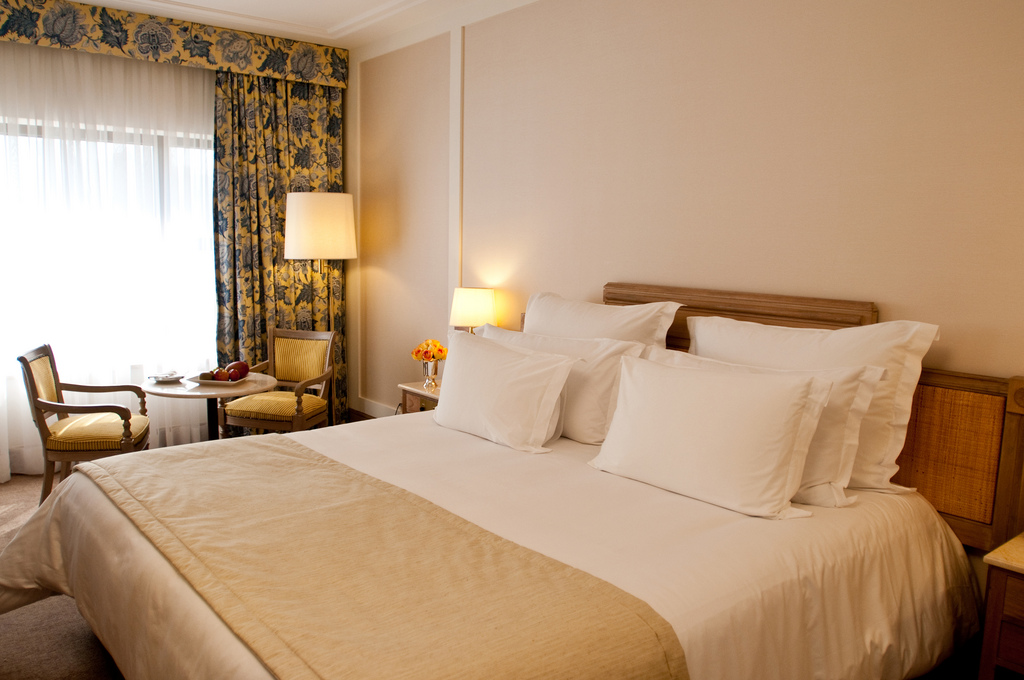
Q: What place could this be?
A: It is a hotel room.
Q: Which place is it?
A: It is a hotel room.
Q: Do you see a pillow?
A: Yes, there is a pillow.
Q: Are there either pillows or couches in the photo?
A: Yes, there is a pillow.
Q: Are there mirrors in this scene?
A: No, there are no mirrors.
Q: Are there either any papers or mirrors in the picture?
A: No, there are no mirrors or papers.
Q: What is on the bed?
A: The pillow is on the bed.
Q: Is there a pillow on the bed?
A: Yes, there is a pillow on the bed.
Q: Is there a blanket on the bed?
A: No, there is a pillow on the bed.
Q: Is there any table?
A: Yes, there is a table.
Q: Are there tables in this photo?
A: Yes, there is a table.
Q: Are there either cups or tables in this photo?
A: Yes, there is a table.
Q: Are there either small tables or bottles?
A: Yes, there is a small table.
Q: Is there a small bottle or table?
A: Yes, there is a small table.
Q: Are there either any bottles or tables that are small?
A: Yes, the table is small.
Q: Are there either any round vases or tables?
A: Yes, there is a round table.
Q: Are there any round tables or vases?
A: Yes, there is a round table.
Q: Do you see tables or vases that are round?
A: Yes, the table is round.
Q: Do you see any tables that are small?
A: Yes, there is a small table.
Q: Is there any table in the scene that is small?
A: Yes, there is a table that is small.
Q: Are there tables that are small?
A: Yes, there is a table that is small.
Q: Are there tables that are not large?
A: Yes, there is a small table.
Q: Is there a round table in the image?
A: Yes, there is a round table.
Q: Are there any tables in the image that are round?
A: Yes, there is a table that is round.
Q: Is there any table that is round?
A: Yes, there is a table that is round.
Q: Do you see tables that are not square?
A: Yes, there is a round table.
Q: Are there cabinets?
A: No, there are no cabinets.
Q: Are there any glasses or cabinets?
A: No, there are no cabinets or glasses.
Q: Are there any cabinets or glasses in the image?
A: No, there are no cabinets or glasses.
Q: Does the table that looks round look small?
A: Yes, the table is small.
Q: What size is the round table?
A: The table is small.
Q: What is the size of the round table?
A: The table is small.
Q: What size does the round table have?
A: The table has small size.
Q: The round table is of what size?
A: The table is small.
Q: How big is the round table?
A: The table is small.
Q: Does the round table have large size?
A: No, the table is small.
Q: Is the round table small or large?
A: The table is small.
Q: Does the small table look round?
A: Yes, the table is round.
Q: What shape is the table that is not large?
A: The table is round.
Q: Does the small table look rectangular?
A: No, the table is round.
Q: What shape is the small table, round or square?
A: The table is round.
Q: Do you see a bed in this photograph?
A: Yes, there is a bed.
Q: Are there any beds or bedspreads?
A: Yes, there is a bed.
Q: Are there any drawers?
A: No, there are no drawers.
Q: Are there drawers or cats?
A: No, there are no drawers or cats.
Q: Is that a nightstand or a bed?
A: That is a bed.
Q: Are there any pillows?
A: Yes, there is a pillow.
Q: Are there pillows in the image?
A: Yes, there is a pillow.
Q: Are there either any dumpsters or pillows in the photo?
A: Yes, there is a pillow.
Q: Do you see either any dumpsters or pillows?
A: Yes, there is a pillow.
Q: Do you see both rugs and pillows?
A: No, there is a pillow but no rugs.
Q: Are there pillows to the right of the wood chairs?
A: Yes, there is a pillow to the right of the chairs.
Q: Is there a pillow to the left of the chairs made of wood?
A: No, the pillow is to the right of the chairs.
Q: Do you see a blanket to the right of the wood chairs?
A: No, there is a pillow to the right of the chairs.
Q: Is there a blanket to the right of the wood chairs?
A: No, there is a pillow to the right of the chairs.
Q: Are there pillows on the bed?
A: Yes, there is a pillow on the bed.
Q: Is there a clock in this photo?
A: No, there are no clocks.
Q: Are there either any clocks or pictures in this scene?
A: No, there are no clocks or pictures.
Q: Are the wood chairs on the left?
A: Yes, the chairs are on the left of the image.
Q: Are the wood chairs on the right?
A: No, the chairs are on the left of the image.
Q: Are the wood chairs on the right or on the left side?
A: The chairs are on the left of the image.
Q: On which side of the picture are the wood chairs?
A: The chairs are on the left of the image.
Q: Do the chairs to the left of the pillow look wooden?
A: Yes, the chairs are wooden.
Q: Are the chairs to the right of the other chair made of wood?
A: Yes, the chairs are made of wood.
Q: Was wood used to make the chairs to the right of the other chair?
A: Yes, the chairs are made of wood.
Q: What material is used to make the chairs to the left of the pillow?
A: The chairs are made of wood.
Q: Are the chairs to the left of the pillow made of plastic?
A: No, the chairs are made of wood.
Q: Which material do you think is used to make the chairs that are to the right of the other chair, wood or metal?
A: The chairs are made of wood.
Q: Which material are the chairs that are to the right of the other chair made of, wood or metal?
A: The chairs are made of wood.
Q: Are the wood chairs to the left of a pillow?
A: Yes, the chairs are to the left of a pillow.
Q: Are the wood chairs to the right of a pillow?
A: No, the chairs are to the left of a pillow.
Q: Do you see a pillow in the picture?
A: Yes, there is a pillow.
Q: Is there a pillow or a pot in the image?
A: Yes, there is a pillow.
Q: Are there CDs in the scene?
A: No, there are no cds.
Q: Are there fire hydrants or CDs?
A: No, there are no CDs or fire hydrants.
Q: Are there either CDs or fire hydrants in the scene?
A: No, there are no CDs or fire hydrants.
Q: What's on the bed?
A: The pillow is on the bed.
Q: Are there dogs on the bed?
A: No, there is a pillow on the bed.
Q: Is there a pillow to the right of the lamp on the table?
A: Yes, there is a pillow to the right of the lamp.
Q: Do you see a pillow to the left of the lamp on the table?
A: No, the pillow is to the right of the lamp.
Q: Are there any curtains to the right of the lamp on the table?
A: No, there is a pillow to the right of the lamp.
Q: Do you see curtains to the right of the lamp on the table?
A: No, there is a pillow to the right of the lamp.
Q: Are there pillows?
A: Yes, there is a pillow.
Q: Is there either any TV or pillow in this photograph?
A: Yes, there is a pillow.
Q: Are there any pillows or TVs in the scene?
A: Yes, there is a pillow.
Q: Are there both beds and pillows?
A: Yes, there are both a pillow and a bed.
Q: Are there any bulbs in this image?
A: No, there are no bulbs.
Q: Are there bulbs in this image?
A: No, there are no bulbs.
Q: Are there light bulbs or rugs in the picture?
A: No, there are no light bulbs or rugs.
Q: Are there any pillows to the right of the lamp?
A: Yes, there is a pillow to the right of the lamp.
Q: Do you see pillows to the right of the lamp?
A: Yes, there is a pillow to the right of the lamp.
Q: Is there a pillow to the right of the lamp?
A: Yes, there is a pillow to the right of the lamp.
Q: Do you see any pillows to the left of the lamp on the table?
A: No, the pillow is to the right of the lamp.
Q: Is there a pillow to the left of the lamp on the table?
A: No, the pillow is to the right of the lamp.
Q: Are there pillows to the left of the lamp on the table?
A: No, the pillow is to the right of the lamp.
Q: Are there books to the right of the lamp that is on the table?
A: No, there is a pillow to the right of the lamp.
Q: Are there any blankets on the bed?
A: No, there is a pillow on the bed.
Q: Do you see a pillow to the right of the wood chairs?
A: Yes, there is a pillow to the right of the chairs.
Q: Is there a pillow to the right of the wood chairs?
A: Yes, there is a pillow to the right of the chairs.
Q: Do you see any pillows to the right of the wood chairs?
A: Yes, there is a pillow to the right of the chairs.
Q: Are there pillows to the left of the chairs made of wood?
A: No, the pillow is to the right of the chairs.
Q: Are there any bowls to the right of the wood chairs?
A: No, there is a pillow to the right of the chairs.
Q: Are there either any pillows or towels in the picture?
A: Yes, there is a pillow.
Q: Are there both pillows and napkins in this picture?
A: No, there is a pillow but no napkins.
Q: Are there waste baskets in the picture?
A: No, there are no waste baskets.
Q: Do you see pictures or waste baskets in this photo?
A: No, there are no waste baskets or pictures.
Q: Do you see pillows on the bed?
A: Yes, there is a pillow on the bed.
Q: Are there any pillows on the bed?
A: Yes, there is a pillow on the bed.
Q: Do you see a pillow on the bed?
A: Yes, there is a pillow on the bed.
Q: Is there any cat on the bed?
A: No, there is a pillow on the bed.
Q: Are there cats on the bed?
A: No, there is a pillow on the bed.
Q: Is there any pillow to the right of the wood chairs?
A: Yes, there is a pillow to the right of the chairs.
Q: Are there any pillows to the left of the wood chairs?
A: No, the pillow is to the right of the chairs.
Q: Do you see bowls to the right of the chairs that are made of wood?
A: No, there is a pillow to the right of the chairs.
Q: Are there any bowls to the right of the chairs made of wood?
A: No, there is a pillow to the right of the chairs.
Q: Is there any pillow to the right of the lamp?
A: Yes, there is a pillow to the right of the lamp.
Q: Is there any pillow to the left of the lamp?
A: No, the pillow is to the right of the lamp.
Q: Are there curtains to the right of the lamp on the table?
A: No, there is a pillow to the right of the lamp.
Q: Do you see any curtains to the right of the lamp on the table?
A: No, there is a pillow to the right of the lamp.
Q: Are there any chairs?
A: Yes, there is a chair.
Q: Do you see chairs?
A: Yes, there is a chair.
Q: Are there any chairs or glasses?
A: Yes, there is a chair.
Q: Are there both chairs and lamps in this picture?
A: Yes, there are both a chair and a lamp.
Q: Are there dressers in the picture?
A: No, there are no dressers.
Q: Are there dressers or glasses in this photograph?
A: No, there are no dressers or glasses.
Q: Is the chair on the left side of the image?
A: Yes, the chair is on the left of the image.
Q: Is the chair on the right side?
A: No, the chair is on the left of the image.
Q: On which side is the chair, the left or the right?
A: The chair is on the left of the image.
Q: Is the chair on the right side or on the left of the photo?
A: The chair is on the left of the image.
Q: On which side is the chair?
A: The chair is on the left of the image.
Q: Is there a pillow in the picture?
A: Yes, there is a pillow.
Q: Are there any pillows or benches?
A: Yes, there is a pillow.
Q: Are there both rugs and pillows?
A: No, there is a pillow but no rugs.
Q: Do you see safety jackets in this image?
A: No, there are no safety jackets.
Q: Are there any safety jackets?
A: No, there are no safety jackets.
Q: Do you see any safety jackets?
A: No, there are no safety jackets.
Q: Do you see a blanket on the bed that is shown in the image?
A: No, there is a pillow on the bed.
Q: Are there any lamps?
A: Yes, there is a lamp.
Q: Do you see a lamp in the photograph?
A: Yes, there is a lamp.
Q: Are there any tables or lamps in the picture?
A: Yes, there is a lamp.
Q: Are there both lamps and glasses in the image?
A: No, there is a lamp but no glasses.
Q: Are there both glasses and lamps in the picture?
A: No, there is a lamp but no glasses.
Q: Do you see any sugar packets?
A: No, there are no sugar packets.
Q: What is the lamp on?
A: The lamp is on the table.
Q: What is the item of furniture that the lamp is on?
A: The piece of furniture is a table.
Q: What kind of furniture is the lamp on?
A: The lamp is on the table.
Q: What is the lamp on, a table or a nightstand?
A: The lamp is on a table.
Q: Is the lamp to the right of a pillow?
A: No, the lamp is to the left of a pillow.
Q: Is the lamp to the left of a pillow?
A: Yes, the lamp is to the left of a pillow.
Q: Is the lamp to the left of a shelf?
A: No, the lamp is to the left of a pillow.